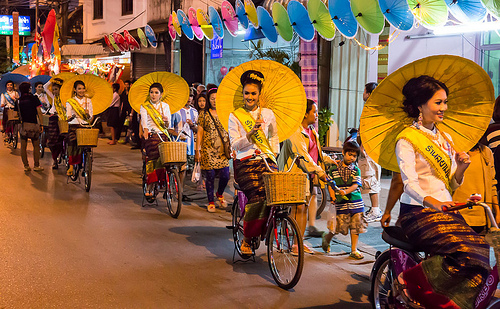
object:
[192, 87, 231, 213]
women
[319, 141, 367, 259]
boy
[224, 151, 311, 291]
bicycle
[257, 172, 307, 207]
basket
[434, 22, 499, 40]
light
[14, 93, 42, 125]
shirt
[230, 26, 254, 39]
lights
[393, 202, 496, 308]
dress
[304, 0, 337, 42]
umbrella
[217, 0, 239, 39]
umbrellas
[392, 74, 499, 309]
girl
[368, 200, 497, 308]
bike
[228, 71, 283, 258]
girl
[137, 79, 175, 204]
girl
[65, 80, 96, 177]
girl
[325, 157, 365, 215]
shirt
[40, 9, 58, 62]
umbrella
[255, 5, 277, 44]
umbrella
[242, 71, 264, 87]
flowers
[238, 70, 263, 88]
hair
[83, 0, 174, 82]
building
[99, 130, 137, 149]
edge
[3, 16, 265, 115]
road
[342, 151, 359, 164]
face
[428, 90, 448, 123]
face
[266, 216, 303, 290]
wheel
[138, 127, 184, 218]
bike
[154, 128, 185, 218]
front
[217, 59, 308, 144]
umbrella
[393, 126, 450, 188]
sash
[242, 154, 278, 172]
handles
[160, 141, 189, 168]
basket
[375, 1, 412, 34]
umbrella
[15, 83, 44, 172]
man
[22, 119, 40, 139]
bag